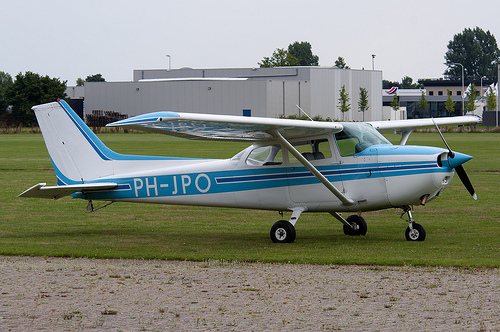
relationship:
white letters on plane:
[128, 169, 218, 201] [19, 80, 499, 257]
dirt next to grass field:
[4, 256, 499, 330] [2, 131, 499, 262]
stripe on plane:
[215, 164, 438, 183] [211, 161, 442, 186]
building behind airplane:
[120, 46, 394, 146] [16, 99, 483, 243]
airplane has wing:
[16, 99, 483, 243] [102, 109, 480, 143]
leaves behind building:
[441, 26, 500, 81] [421, 75, 496, 102]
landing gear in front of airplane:
[400, 204, 426, 241] [16, 99, 483, 243]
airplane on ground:
[10, 88, 484, 250] [2, 125, 499, 330]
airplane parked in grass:
[16, 99, 483, 243] [0, 125, 500, 269]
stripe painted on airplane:
[56, 100, 109, 160] [17, 97, 482, 242]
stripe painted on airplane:
[106, 115, 159, 125] [17, 97, 482, 242]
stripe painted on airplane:
[214, 162, 439, 185] [17, 97, 482, 242]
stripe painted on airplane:
[55, 177, 130, 189] [17, 97, 482, 242]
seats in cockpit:
[295, 128, 343, 163] [240, 127, 390, 166]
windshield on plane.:
[334, 123, 391, 156] [10, 64, 469, 258]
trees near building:
[335, 85, 349, 118] [79, 61, 406, 136]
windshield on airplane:
[336, 120, 389, 164] [10, 88, 484, 250]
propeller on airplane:
[431, 117, 477, 202] [16, 99, 483, 243]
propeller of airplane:
[432, 117, 478, 200] [16, 99, 483, 243]